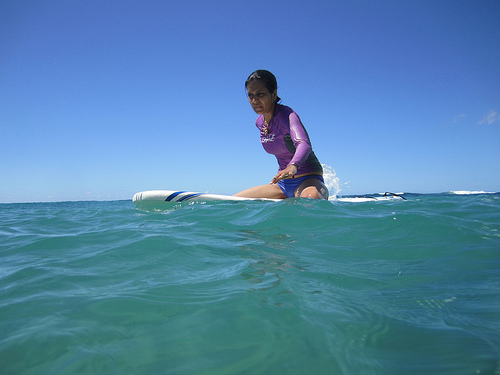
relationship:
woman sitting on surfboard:
[229, 68, 328, 201] [131, 189, 401, 202]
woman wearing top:
[229, 68, 328, 201] [254, 102, 324, 176]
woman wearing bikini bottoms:
[229, 68, 328, 201] [272, 170, 323, 200]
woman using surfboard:
[229, 68, 328, 201] [131, 189, 401, 202]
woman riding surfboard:
[229, 68, 328, 201] [131, 189, 401, 202]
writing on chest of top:
[258, 132, 277, 145] [254, 102, 324, 176]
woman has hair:
[229, 68, 328, 201] [245, 66, 281, 105]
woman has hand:
[229, 68, 328, 201] [271, 162, 298, 184]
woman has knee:
[229, 68, 328, 201] [300, 189, 324, 201]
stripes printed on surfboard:
[164, 188, 206, 202] [131, 189, 401, 202]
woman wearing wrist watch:
[229, 68, 328, 201] [287, 161, 301, 173]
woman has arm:
[229, 68, 328, 201] [271, 112, 313, 175]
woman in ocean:
[229, 68, 328, 201] [0, 189, 498, 374]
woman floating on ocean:
[229, 68, 328, 201] [0, 189, 498, 374]